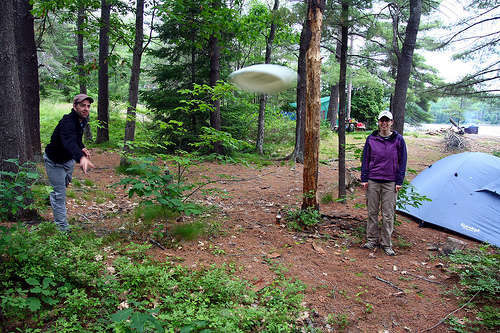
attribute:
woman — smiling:
[358, 111, 409, 255]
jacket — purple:
[361, 131, 408, 185]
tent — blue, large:
[396, 151, 499, 253]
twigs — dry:
[371, 269, 442, 300]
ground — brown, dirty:
[7, 126, 494, 332]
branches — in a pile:
[442, 134, 480, 152]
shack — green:
[285, 97, 351, 126]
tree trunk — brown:
[1, 2, 43, 222]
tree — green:
[120, 82, 248, 233]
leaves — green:
[122, 84, 263, 174]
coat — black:
[45, 110, 88, 161]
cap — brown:
[73, 94, 94, 106]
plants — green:
[1, 224, 302, 331]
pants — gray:
[367, 181, 397, 249]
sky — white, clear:
[109, 4, 498, 93]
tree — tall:
[96, 1, 110, 145]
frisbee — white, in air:
[225, 61, 295, 96]